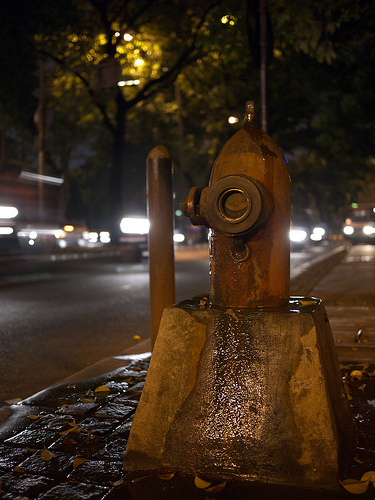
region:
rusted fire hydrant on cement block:
[128, 113, 349, 473]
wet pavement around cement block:
[15, 338, 373, 490]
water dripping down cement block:
[133, 300, 333, 470]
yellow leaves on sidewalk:
[28, 346, 373, 485]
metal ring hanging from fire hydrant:
[225, 241, 251, 263]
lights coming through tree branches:
[78, 11, 170, 94]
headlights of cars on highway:
[280, 213, 373, 251]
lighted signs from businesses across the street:
[1, 197, 178, 247]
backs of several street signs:
[23, 50, 57, 232]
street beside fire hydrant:
[16, 228, 296, 385]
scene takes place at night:
[4, 4, 373, 474]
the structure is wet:
[176, 302, 346, 483]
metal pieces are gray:
[172, 167, 279, 255]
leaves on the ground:
[6, 322, 348, 491]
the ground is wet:
[4, 334, 328, 485]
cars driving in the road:
[281, 207, 372, 274]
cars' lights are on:
[8, 215, 370, 256]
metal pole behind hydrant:
[135, 134, 180, 360]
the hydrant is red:
[204, 92, 305, 343]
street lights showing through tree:
[87, 23, 160, 100]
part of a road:
[76, 341, 87, 350]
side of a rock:
[287, 407, 311, 418]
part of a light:
[311, 226, 330, 243]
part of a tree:
[338, 93, 354, 104]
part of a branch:
[119, 97, 135, 120]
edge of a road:
[25, 376, 33, 393]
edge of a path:
[69, 419, 102, 464]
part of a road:
[53, 422, 70, 438]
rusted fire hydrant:
[183, 93, 312, 306]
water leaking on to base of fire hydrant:
[140, 301, 334, 483]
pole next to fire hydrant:
[139, 153, 175, 342]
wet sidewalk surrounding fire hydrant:
[24, 346, 373, 497]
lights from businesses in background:
[3, 183, 164, 268]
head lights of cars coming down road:
[283, 198, 369, 240]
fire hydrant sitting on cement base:
[132, 98, 338, 483]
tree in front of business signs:
[42, 9, 201, 257]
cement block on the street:
[114, 286, 354, 488]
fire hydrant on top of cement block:
[168, 97, 311, 320]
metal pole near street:
[139, 143, 185, 365]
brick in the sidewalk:
[0, 419, 60, 455]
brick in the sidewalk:
[46, 470, 111, 498]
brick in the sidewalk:
[95, 396, 135, 423]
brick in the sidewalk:
[66, 409, 119, 439]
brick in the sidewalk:
[5, 467, 54, 498]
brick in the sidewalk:
[0, 438, 38, 474]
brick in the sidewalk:
[126, 377, 152, 395]